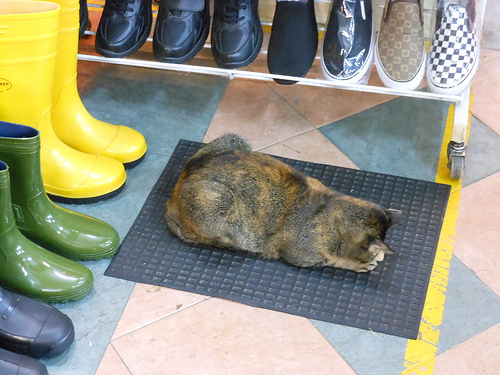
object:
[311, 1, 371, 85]
shoe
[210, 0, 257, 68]
shoe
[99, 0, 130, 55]
shoe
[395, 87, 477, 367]
yellow stripe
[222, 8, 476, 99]
shoes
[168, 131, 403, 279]
calico cat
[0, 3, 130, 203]
boot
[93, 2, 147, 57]
shoe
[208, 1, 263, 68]
shoe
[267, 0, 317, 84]
shoe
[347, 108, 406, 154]
tile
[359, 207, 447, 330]
mat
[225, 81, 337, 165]
tile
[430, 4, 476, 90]
checkered shoe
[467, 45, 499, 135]
tile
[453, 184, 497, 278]
red tile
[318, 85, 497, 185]
black tile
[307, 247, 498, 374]
black tile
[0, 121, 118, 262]
green boots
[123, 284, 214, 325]
tile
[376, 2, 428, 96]
shoe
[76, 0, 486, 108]
shoe rack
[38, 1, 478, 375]
floor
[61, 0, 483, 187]
rack